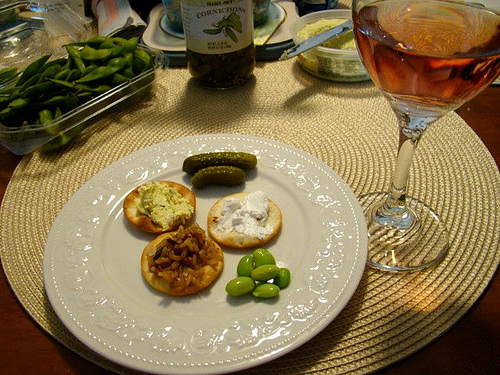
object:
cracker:
[207, 190, 282, 248]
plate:
[41, 134, 371, 375]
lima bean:
[251, 282, 279, 298]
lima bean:
[235, 252, 254, 276]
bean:
[225, 276, 255, 297]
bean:
[253, 248, 275, 267]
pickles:
[182, 152, 258, 176]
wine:
[350, 1, 499, 100]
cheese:
[212, 190, 275, 241]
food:
[224, 246, 288, 300]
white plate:
[31, 139, 405, 370]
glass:
[354, 0, 500, 271]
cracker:
[141, 231, 225, 295]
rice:
[148, 222, 218, 291]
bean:
[252, 283, 280, 297]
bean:
[250, 264, 279, 281]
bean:
[274, 268, 291, 289]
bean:
[237, 254, 254, 277]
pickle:
[191, 166, 246, 188]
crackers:
[123, 180, 196, 233]